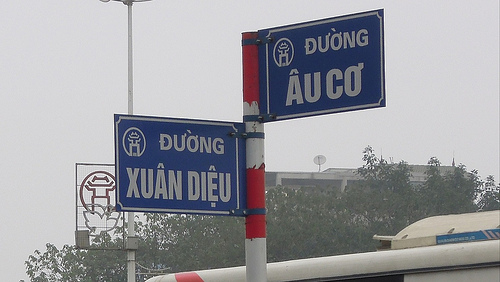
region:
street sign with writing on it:
[110, 110, 255, 225]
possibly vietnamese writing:
[110, 105, 252, 230]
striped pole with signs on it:
[235, 22, 270, 273]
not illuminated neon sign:
[73, 150, 143, 267]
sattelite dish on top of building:
[298, 143, 340, 174]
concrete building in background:
[265, 161, 486, 211]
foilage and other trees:
[20, 231, 115, 276]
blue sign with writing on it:
[423, 226, 495, 251]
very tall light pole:
[113, 0, 148, 280]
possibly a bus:
[146, 240, 498, 280]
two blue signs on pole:
[64, 3, 496, 276]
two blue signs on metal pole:
[110, 18, 444, 232]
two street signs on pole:
[68, 11, 453, 276]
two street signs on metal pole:
[57, 2, 498, 270]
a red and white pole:
[172, 22, 289, 278]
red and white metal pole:
[224, 17, 317, 281]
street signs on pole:
[51, 16, 488, 221]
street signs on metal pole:
[117, 28, 437, 240]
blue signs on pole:
[89, 10, 493, 224]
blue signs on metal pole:
[62, 14, 499, 257]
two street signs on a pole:
[68, 14, 430, 279]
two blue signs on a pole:
[137, 45, 471, 257]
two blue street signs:
[92, 20, 447, 231]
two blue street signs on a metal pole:
[105, 0, 458, 267]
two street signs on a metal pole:
[90, 32, 457, 280]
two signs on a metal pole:
[127, 4, 417, 244]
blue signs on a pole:
[57, 2, 436, 279]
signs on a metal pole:
[54, 17, 485, 281]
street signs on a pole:
[87, 2, 490, 219]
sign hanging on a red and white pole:
[231, 5, 419, 147]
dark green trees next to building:
[347, 146, 496, 243]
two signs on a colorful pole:
[108, 0, 388, 265]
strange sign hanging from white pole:
[68, 151, 135, 272]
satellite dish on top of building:
[299, 136, 327, 167]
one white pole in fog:
[53, 2, 188, 89]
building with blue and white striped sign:
[385, 214, 495, 271]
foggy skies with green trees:
[291, 137, 475, 208]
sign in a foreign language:
[219, 9, 396, 124]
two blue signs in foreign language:
[94, 0, 434, 231]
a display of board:
[238, 15, 421, 127]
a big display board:
[93, 104, 271, 254]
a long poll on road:
[237, 81, 275, 271]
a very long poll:
[111, 7, 166, 252]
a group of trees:
[76, 152, 487, 267]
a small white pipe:
[239, 240, 495, 278]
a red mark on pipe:
[244, 171, 266, 246]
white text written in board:
[129, 133, 261, 225]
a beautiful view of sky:
[34, 10, 448, 180]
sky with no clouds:
[51, 23, 481, 183]